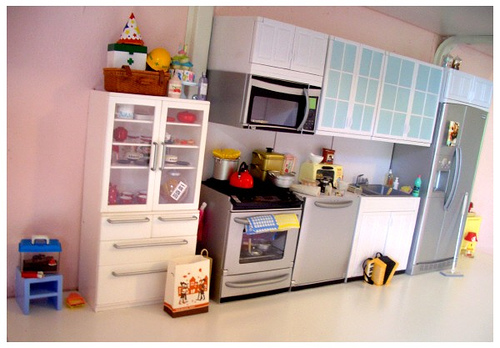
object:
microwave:
[205, 71, 324, 138]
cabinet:
[248, 21, 295, 71]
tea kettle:
[226, 160, 254, 190]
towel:
[242, 213, 279, 238]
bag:
[160, 248, 212, 319]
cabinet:
[104, 101, 161, 213]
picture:
[443, 120, 460, 148]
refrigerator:
[381, 100, 487, 276]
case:
[370, 254, 401, 287]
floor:
[9, 245, 492, 342]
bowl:
[177, 112, 194, 125]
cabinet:
[152, 99, 213, 211]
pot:
[273, 174, 296, 189]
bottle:
[198, 72, 212, 104]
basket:
[103, 67, 171, 98]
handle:
[103, 215, 151, 226]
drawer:
[100, 218, 154, 242]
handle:
[157, 213, 200, 224]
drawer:
[151, 212, 205, 239]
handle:
[110, 240, 188, 249]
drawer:
[98, 234, 200, 267]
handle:
[108, 264, 171, 280]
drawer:
[95, 259, 175, 303]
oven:
[201, 177, 305, 303]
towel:
[273, 213, 301, 233]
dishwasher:
[286, 181, 359, 293]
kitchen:
[0, 0, 499, 347]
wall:
[3, 6, 495, 301]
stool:
[14, 268, 66, 315]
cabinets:
[318, 34, 358, 135]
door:
[350, 46, 388, 137]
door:
[371, 53, 414, 142]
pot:
[210, 151, 239, 183]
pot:
[250, 148, 282, 187]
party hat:
[113, 12, 143, 45]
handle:
[234, 159, 250, 180]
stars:
[113, 36, 143, 46]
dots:
[129, 23, 133, 30]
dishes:
[166, 159, 191, 168]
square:
[325, 41, 341, 72]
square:
[321, 67, 339, 99]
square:
[317, 98, 335, 131]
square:
[380, 55, 402, 86]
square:
[413, 63, 430, 93]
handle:
[231, 215, 302, 224]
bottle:
[411, 173, 422, 197]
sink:
[350, 184, 413, 198]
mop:
[436, 192, 468, 277]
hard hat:
[144, 47, 173, 74]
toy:
[167, 46, 193, 71]